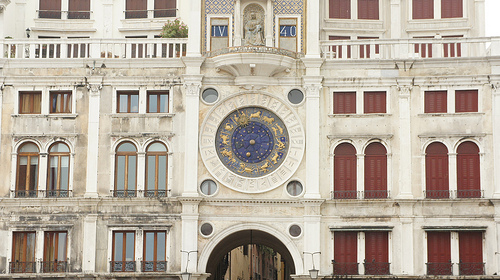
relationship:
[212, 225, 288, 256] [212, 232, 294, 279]
arch on doorway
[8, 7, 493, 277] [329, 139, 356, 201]
building has window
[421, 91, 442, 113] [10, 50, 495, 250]
window on building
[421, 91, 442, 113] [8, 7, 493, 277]
window on building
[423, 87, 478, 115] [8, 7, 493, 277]
window on building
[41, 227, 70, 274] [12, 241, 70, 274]
window has railing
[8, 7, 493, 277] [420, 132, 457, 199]
building has window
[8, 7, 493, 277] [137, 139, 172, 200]
building has window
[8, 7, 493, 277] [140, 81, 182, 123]
building has window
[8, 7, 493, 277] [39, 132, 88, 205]
building has window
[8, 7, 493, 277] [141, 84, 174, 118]
building has window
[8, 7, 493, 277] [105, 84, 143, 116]
building has window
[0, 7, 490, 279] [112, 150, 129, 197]
building has window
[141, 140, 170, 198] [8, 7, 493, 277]
window on building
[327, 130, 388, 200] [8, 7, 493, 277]
window on building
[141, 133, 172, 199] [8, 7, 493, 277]
window on building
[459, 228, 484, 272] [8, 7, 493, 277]
window on building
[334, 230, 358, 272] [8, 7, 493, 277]
window on building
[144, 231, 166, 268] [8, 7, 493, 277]
window on building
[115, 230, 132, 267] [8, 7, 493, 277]
window on building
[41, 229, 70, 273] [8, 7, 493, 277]
window on building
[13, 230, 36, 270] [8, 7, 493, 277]
window on building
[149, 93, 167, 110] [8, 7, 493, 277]
window on building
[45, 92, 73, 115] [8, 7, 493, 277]
window on building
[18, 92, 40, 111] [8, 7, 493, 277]
window on building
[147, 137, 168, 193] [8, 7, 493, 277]
window on building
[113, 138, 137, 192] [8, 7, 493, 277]
window on building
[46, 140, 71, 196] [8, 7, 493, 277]
window on building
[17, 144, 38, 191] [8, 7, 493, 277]
window on building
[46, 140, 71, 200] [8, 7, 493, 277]
window on building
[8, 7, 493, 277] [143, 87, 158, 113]
building has window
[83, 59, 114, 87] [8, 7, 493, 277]
design on building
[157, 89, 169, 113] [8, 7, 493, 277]
window on building